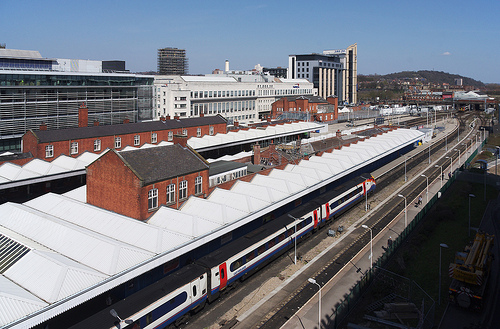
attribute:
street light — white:
[304, 273, 324, 325]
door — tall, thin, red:
[215, 257, 232, 287]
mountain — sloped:
[367, 65, 473, 102]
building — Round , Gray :
[158, 46, 185, 71]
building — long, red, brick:
[20, 114, 230, 165]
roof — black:
[21, 112, 227, 144]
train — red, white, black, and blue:
[62, 165, 397, 327]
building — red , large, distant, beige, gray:
[282, 40, 362, 102]